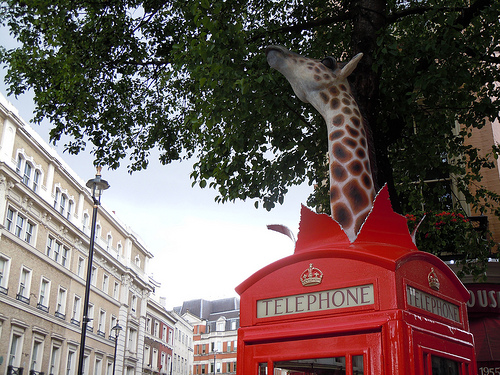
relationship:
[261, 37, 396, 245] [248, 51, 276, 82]
giraffe eatin leaves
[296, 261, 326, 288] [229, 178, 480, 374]
crown on cabin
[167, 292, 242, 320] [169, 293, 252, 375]
roof of buildings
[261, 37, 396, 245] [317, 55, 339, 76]
giraffe has eye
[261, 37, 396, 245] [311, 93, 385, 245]
giraffe has neck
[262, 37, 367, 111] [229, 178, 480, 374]
head through cabin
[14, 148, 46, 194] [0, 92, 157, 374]
windows on buildings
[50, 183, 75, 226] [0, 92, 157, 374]
windows on buildings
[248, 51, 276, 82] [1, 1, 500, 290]
leaves on tree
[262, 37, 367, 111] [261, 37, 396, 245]
head of giraffe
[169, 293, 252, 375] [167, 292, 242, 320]
buildings with roof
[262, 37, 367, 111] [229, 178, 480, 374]
head poked thru top cabin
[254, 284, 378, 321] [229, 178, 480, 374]
telephone on cabin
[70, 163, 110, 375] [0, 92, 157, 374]
pole near buildings